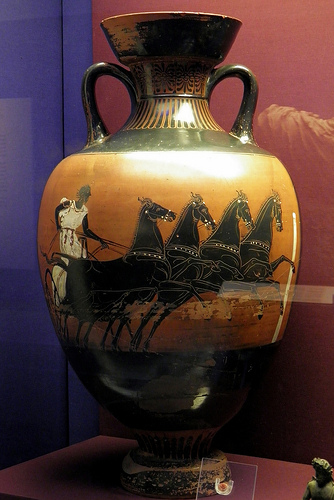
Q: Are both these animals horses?
A: Yes, all the animals are horses.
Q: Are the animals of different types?
A: No, all the animals are horses.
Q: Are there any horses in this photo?
A: Yes, there is a horse.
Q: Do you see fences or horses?
A: Yes, there is a horse.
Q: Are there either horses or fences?
A: Yes, there is a horse.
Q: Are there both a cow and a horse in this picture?
A: No, there is a horse but no cows.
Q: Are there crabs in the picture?
A: No, there are no crabs.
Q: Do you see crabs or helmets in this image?
A: No, there are no crabs or helmets.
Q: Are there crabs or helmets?
A: No, there are no crabs or helmets.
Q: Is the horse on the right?
A: Yes, the horse is on the right of the image.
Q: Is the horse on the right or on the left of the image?
A: The horse is on the right of the image.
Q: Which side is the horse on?
A: The horse is on the right of the image.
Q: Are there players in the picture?
A: No, there are no players.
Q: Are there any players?
A: No, there are no players.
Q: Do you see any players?
A: No, there are no players.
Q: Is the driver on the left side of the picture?
A: Yes, the driver is on the left of the image.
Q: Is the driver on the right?
A: No, the driver is on the left of the image.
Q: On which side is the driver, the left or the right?
A: The driver is on the left of the image.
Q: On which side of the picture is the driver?
A: The driver is on the left of the image.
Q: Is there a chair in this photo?
A: No, there are no chairs.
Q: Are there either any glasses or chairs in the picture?
A: No, there are no chairs or glasses.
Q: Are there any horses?
A: Yes, there is a horse.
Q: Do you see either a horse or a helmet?
A: Yes, there is a horse.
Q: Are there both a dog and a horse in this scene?
A: No, there is a horse but no dogs.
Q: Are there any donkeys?
A: No, there are no donkeys.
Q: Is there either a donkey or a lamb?
A: No, there are no donkeys or lambs.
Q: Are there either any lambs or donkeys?
A: No, there are no donkeys or lambs.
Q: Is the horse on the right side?
A: Yes, the horse is on the right of the image.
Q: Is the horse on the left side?
A: No, the horse is on the right of the image.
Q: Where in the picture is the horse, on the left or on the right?
A: The horse is on the right of the image.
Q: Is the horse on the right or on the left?
A: The horse is on the right of the image.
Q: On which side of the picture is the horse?
A: The horse is on the right of the image.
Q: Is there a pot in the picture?
A: Yes, there is a pot.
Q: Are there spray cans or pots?
A: Yes, there is a pot.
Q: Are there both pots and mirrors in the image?
A: No, there is a pot but no mirrors.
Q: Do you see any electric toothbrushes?
A: No, there are no electric toothbrushes.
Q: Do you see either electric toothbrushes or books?
A: No, there are no electric toothbrushes or books.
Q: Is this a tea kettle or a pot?
A: This is a pot.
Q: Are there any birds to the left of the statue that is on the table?
A: No, there is a pot to the left of the statue.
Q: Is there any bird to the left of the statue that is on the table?
A: No, there is a pot to the left of the statue.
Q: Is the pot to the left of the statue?
A: Yes, the pot is to the left of the statue.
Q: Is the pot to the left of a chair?
A: No, the pot is to the left of the statue.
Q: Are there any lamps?
A: No, there are no lamps.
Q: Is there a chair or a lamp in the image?
A: No, there are no lamps or chairs.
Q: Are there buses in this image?
A: No, there are no buses.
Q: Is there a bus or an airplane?
A: No, there are no buses or airplanes.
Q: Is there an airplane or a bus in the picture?
A: No, there are no buses or airplanes.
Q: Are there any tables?
A: Yes, there is a table.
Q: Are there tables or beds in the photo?
A: Yes, there is a table.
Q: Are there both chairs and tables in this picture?
A: No, there is a table but no chairs.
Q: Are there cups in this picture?
A: No, there are no cups.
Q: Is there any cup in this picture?
A: No, there are no cups.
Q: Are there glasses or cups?
A: No, there are no cups or glasses.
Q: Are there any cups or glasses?
A: No, there are no cups or glasses.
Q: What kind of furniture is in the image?
A: The furniture is a table.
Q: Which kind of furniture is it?
A: The piece of furniture is a table.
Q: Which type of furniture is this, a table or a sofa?
A: That is a table.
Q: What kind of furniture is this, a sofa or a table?
A: That is a table.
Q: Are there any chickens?
A: No, there are no chickens.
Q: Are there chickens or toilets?
A: No, there are no chickens or toilets.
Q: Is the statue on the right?
A: Yes, the statue is on the right of the image.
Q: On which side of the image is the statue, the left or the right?
A: The statue is on the right of the image.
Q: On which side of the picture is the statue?
A: The statue is on the right of the image.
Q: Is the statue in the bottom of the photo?
A: Yes, the statue is in the bottom of the image.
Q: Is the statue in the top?
A: No, the statue is in the bottom of the image.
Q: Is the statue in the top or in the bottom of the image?
A: The statue is in the bottom of the image.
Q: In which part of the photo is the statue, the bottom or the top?
A: The statue is in the bottom of the image.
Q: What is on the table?
A: The statue is on the table.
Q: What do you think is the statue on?
A: The statue is on the table.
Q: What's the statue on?
A: The statue is on the table.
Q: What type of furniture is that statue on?
A: The statue is on the table.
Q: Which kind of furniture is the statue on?
A: The statue is on the table.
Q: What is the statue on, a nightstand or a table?
A: The statue is on a table.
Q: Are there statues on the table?
A: Yes, there is a statue on the table.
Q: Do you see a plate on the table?
A: No, there is a statue on the table.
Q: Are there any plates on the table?
A: No, there is a statue on the table.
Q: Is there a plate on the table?
A: No, there is a statue on the table.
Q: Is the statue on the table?
A: Yes, the statue is on the table.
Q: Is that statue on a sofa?
A: No, the statue is on the table.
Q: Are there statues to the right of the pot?
A: Yes, there is a statue to the right of the pot.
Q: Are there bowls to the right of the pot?
A: No, there is a statue to the right of the pot.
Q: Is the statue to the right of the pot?
A: Yes, the statue is to the right of the pot.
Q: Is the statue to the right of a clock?
A: No, the statue is to the right of the pot.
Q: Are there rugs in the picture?
A: No, there are no rugs.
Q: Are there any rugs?
A: No, there are no rugs.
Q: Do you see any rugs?
A: No, there are no rugs.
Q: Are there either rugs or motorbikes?
A: No, there are no rugs or motorbikes.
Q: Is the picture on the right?
A: Yes, the picture is on the right of the image.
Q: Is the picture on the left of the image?
A: No, the picture is on the right of the image.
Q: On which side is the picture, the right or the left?
A: The picture is on the right of the image.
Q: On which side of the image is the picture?
A: The picture is on the right of the image.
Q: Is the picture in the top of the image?
A: Yes, the picture is in the top of the image.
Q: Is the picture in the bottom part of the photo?
A: No, the picture is in the top of the image.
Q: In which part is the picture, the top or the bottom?
A: The picture is in the top of the image.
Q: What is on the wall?
A: The picture is on the wall.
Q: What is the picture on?
A: The picture is on the wall.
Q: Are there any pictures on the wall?
A: Yes, there is a picture on the wall.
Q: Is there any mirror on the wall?
A: No, there is a picture on the wall.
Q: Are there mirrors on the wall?
A: No, there is a picture on the wall.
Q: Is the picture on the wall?
A: Yes, the picture is on the wall.